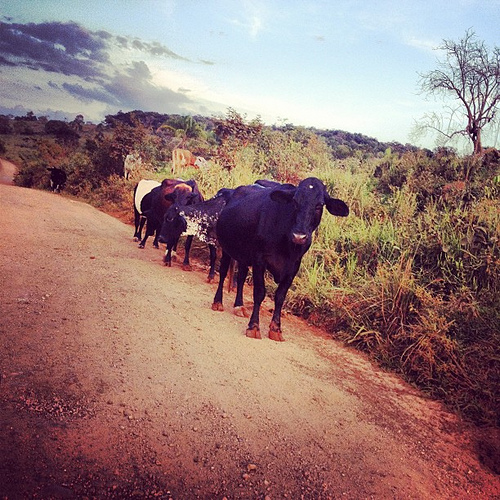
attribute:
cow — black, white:
[165, 200, 221, 278]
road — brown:
[142, 282, 219, 485]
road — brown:
[305, 408, 332, 443]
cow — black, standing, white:
[211, 177, 349, 341]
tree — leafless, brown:
[408, 25, 498, 175]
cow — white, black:
[196, 171, 351, 345]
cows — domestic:
[100, 160, 366, 355]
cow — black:
[164, 203, 236, 268]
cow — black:
[214, 175, 371, 323]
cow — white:
[127, 170, 177, 227]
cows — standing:
[211, 175, 349, 342]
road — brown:
[1, 158, 497, 498]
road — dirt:
[4, 340, 439, 494]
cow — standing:
[204, 164, 353, 354]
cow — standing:
[148, 184, 230, 278]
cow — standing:
[139, 167, 189, 250]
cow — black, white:
[206, 146, 387, 326]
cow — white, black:
[205, 170, 326, 351]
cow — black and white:
[131, 167, 343, 285]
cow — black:
[212, 164, 357, 349]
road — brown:
[13, 257, 233, 464]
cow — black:
[226, 188, 293, 318]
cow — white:
[135, 184, 161, 227]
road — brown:
[70, 338, 380, 497]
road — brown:
[18, 205, 397, 480]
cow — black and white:
[159, 190, 236, 269]